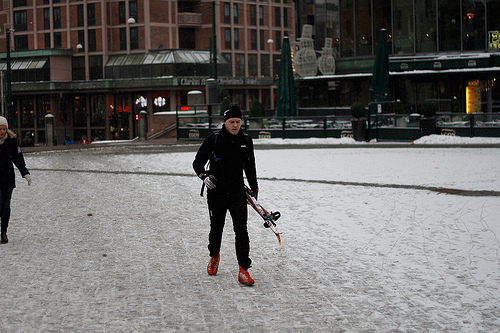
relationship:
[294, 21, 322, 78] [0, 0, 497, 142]
snowman on building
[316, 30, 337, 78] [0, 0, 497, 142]
snowman on building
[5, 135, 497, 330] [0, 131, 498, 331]
snow on ground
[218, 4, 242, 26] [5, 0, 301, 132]
window on building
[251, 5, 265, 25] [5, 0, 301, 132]
window on building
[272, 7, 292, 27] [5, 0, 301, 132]
window on building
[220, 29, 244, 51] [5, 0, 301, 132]
window on building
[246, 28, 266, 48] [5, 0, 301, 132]
window on building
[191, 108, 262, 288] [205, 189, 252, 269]
man has pants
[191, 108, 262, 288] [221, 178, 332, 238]
man carrying skateboard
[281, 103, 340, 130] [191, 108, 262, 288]
fence behind man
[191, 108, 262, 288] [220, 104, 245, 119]
man has hat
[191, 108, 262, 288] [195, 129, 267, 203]
man has shirt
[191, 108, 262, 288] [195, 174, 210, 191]
man has gloves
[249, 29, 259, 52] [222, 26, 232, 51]
window around window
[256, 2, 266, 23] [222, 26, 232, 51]
window around window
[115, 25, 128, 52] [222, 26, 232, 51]
window around window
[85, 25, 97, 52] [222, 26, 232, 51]
window around window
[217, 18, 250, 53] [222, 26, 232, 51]
white frame around window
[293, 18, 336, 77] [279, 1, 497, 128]
snowmen on building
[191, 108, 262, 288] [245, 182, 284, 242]
man carrying skis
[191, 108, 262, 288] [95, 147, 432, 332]
man walking across pavement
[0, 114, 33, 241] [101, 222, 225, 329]
woman walking across pavement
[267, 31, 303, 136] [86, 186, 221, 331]
umbrella on sidewalk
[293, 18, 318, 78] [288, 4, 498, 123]
snowmen on building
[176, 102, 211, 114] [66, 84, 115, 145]
sign in window